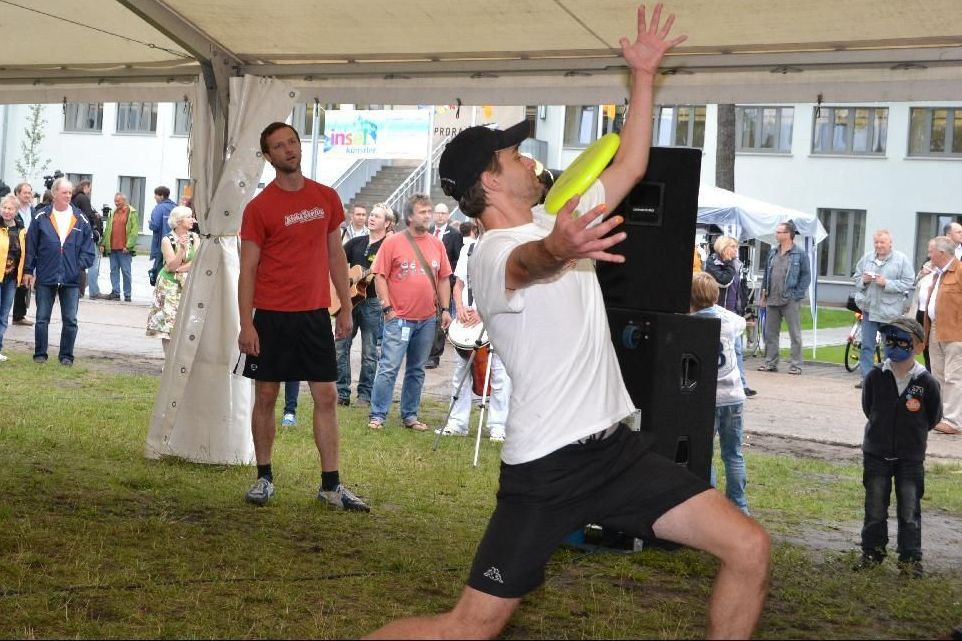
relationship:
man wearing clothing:
[232, 114, 376, 515] [232, 172, 361, 387]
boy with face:
[873, 323, 927, 567] [877, 323, 926, 360]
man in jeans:
[382, 195, 446, 438] [369, 316, 439, 419]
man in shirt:
[382, 195, 446, 438] [369, 231, 444, 320]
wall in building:
[26, 114, 178, 318] [26, 114, 955, 387]